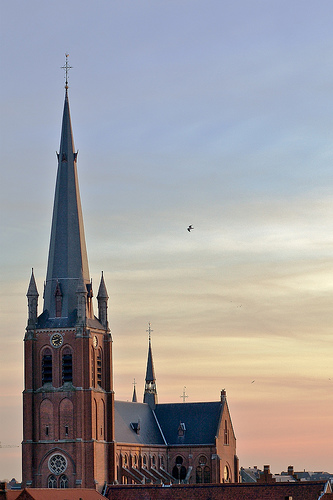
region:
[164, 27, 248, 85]
this is the sky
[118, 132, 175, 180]
the sky is blue in color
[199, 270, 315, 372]
the sky has clouds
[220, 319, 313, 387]
the clouds are white in color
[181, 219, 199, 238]
this is a bird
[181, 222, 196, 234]
the bird is in the air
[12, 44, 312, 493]
this is a building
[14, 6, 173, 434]
the building is tall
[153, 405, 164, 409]
this is a roof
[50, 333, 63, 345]
this is a clock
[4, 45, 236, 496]
A church with a tall steeple.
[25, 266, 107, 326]
Smaller steeples below a large steeple.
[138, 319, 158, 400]
A cross on top of a steeple.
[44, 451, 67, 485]
A round design above two windows.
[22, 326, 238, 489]
A red brick church building.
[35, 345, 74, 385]
Two arched windows.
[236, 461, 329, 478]
Building tops behind the church.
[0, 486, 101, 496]
The edge of two tiled rooftops.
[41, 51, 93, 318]
A cone shaped tower with a cross on top.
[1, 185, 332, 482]
Light clouds with a pink hue in the sky.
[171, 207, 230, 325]
This is a bird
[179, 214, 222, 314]
The bird is small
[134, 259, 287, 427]
This is a sunset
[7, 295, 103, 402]
These are two vents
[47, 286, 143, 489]
This is a clock tower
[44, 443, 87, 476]
This is a round window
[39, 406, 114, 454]
These are small windows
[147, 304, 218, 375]
This is a cross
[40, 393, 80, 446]
The building is brick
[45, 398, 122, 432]
The building is stone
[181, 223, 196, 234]
bird flying in air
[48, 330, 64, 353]
clock on building front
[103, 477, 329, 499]
roof top on lower building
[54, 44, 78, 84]
weather vane at top of building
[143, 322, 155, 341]
cross at top of lower steeple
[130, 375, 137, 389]
cross in distance left of building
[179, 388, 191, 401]
cross in distnace to right of building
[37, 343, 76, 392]
shutters on front windows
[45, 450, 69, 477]
round window on building front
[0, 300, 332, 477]
clouds in sky tinted due to sunset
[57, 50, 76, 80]
cross on top of highest roof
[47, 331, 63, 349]
clock on brick tower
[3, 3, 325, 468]
sky behind the church building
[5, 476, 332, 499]
roof line of buildings in front of church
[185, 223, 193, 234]
bird flying through the air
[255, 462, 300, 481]
brick chimneys on roof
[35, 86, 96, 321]
steeple of clock tower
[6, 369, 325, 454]
pink bands in the sky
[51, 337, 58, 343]
big and little hand on clock face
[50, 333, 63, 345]
number markings on clock face